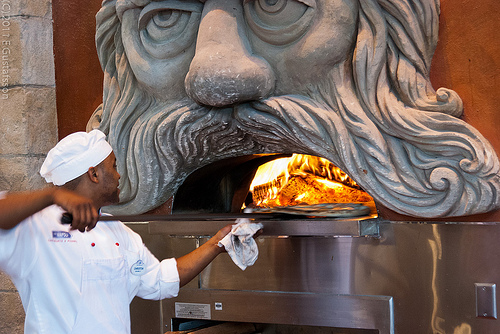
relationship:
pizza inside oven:
[253, 204, 386, 226] [98, 140, 497, 332]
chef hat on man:
[37, 119, 117, 189] [0, 130, 261, 334]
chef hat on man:
[37, 128, 114, 187] [0, 130, 261, 334]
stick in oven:
[201, 191, 374, 231] [172, 138, 384, 232]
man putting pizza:
[21, 141, 159, 328] [268, 202, 372, 217]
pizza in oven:
[268, 202, 372, 217] [162, 120, 439, 282]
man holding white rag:
[0, 130, 261, 334] [216, 212, 268, 271]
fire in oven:
[250, 149, 360, 210] [161, 131, 382, 216]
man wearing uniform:
[0, 130, 261, 334] [26, 215, 106, 321]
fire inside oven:
[250, 153, 377, 217] [146, 122, 444, 324]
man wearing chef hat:
[0, 130, 261, 334] [37, 128, 114, 187]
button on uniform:
[91, 240, 96, 248] [3, 213, 176, 333]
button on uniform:
[113, 242, 122, 246] [3, 213, 176, 333]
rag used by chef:
[216, 207, 263, 271] [0, 129, 262, 332]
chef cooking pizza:
[1, 94, 273, 331] [248, 151, 382, 223]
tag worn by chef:
[124, 251, 151, 281] [1, 94, 273, 331]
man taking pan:
[0, 130, 261, 334] [88, 193, 370, 238]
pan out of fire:
[88, 193, 370, 238] [242, 153, 381, 209]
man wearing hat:
[0, 130, 261, 334] [30, 120, 130, 179]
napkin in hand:
[217, 215, 261, 268] [221, 215, 254, 249]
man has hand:
[0, 130, 261, 334] [221, 215, 254, 249]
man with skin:
[0, 130, 261, 334] [92, 170, 116, 198]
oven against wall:
[56, 3, 498, 223] [54, 1, 484, 221]